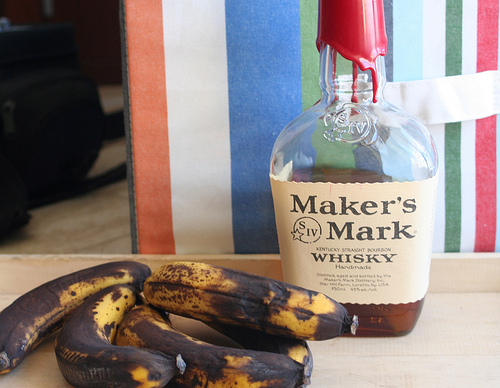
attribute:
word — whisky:
[301, 243, 415, 273]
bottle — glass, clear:
[259, 32, 438, 342]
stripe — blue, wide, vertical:
[230, 17, 300, 259]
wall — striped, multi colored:
[122, 5, 497, 263]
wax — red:
[322, 7, 388, 58]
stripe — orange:
[121, 8, 177, 254]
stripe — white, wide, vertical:
[171, 6, 232, 267]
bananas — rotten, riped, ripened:
[55, 265, 314, 379]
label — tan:
[277, 192, 421, 296]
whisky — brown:
[327, 292, 416, 338]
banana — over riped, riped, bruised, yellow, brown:
[70, 289, 127, 386]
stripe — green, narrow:
[437, 4, 466, 203]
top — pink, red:
[320, 6, 384, 51]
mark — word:
[328, 217, 414, 245]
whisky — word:
[308, 246, 403, 265]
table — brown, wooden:
[95, 258, 474, 383]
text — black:
[327, 216, 402, 294]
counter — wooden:
[263, 259, 490, 383]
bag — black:
[15, 78, 104, 209]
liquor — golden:
[304, 268, 416, 331]